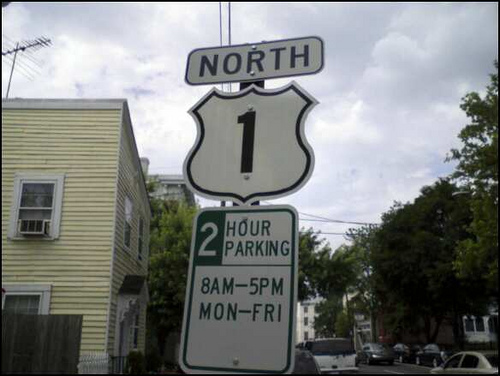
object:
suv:
[305, 337, 360, 372]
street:
[323, 357, 439, 372]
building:
[1, 96, 155, 373]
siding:
[2, 96, 156, 373]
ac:
[18, 219, 49, 238]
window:
[15, 182, 56, 236]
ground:
[420, 202, 431, 215]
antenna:
[0, 34, 53, 99]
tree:
[365, 175, 478, 344]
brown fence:
[0, 309, 85, 376]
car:
[356, 343, 395, 366]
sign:
[184, 35, 325, 85]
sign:
[181, 79, 320, 206]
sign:
[172, 202, 303, 373]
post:
[233, 80, 262, 207]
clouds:
[0, 0, 500, 261]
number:
[198, 222, 218, 256]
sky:
[0, 1, 497, 260]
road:
[322, 363, 433, 374]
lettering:
[199, 45, 309, 78]